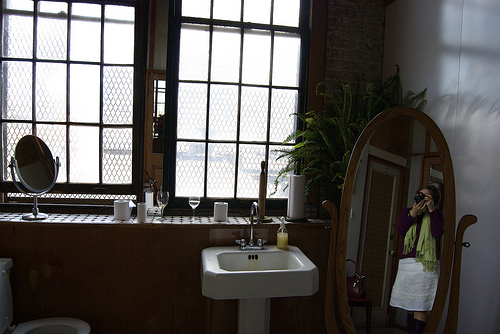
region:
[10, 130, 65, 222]
A table top mirror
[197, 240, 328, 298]
A white ceramic sink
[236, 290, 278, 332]
A white porcelain pedestal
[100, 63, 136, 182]
Glass panes with a metal gate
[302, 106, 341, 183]
A green floor plant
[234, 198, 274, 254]
A stainless steel faucet with hot and cold knobs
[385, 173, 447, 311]
The reflection of a person in the mirror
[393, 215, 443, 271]
Reflection of a green scarf on the mirror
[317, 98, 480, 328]
A dark brown wooden mirror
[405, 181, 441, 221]
A person with a camera in the mirror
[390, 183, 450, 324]
A woman holding a camera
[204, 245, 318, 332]
A white sink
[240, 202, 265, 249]
The silver faucet of a sink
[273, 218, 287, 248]
A soap bottle next to the sink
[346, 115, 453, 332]
A large standing mirror reflecting a woman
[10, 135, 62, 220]
A small mirror on the counter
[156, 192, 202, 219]
Wine glasses on the counter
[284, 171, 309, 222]
A roll of paper towels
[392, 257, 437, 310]
A white skirt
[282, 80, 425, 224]
A potted plant partially behind the mirror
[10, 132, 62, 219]
round makeup mirror on stand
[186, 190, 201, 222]
have full wine glass with clear liquid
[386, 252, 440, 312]
reflection of woman's cotton skirt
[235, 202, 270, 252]
silver single sink faucet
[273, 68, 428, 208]
large green fern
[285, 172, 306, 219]
white paper towel roll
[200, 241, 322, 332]
white porcelain pedestal sink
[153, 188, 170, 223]
empty wine glass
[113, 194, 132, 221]
roll of white toilet paper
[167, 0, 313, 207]
large brown paned window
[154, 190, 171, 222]
Wine glass on window ledge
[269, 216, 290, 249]
Soap bottle on sink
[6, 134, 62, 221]
Mirror on window ledge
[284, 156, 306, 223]
Paper towel roll on window ledge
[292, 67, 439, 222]
Plant behind the mirror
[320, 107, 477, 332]
Oval mirror made of wood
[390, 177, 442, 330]
Woman's reflection in mirror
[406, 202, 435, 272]
Green scarf on woman's neck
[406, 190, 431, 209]
Camera in woman's hand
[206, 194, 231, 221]
White candle on window ledge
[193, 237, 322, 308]
a bathroom sink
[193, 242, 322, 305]
the sink in a bathroom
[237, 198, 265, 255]
the faucet on a bathroom sink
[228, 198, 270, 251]
the faucet in a bathroom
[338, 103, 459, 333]
a mirror in a bathroom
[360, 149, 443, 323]
the image of a woman in a mirror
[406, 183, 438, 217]
a woman taking a picture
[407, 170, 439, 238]
a woman holding a camera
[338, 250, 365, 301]
a woman's purse on a table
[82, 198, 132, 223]
a roll of toilet paper on a shelf